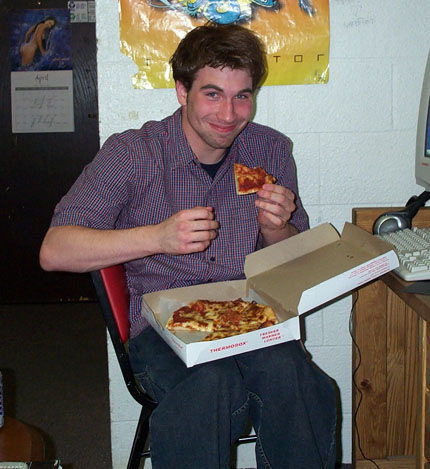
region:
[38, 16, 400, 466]
Man with an open pizza box in his hand.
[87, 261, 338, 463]
A red and black chair.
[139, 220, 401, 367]
Pizza box with an open lid.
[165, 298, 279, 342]
A slice taken out of the pizza.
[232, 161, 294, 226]
A slice of pizza in the hand.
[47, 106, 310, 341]
A red and blue thin striped shirt.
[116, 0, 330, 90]
A yellow poster behind the man's head.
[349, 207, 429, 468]
A brown wooden desk.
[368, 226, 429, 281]
A white computer keyboard on top of the desk.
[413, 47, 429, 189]
Edge of a computer monitor.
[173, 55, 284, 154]
the head of a man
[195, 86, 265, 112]
the eyes of a man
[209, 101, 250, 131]
the nose of a man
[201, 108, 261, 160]
the mouth of a man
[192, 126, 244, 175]
the chin of a man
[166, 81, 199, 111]
the ear of a man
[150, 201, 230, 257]
the hand of a man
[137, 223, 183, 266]
the wrist of a man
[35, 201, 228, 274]
the arm of a man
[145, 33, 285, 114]
the hair of a man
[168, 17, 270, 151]
this young man looks very pleased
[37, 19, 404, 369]
young man enjoying a pizza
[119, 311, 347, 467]
young man wearing baggy jeans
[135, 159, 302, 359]
young man is on his first slice of pizza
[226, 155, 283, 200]
pizza slice is half eaten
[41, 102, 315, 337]
young man wearing a checkered shirt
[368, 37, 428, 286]
young man has a desktop computer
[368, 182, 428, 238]
young man has a pair of over-ear headphones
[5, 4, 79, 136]
young man has a girlie calendar on the wall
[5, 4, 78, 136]
young man's girlie calendar is displaying April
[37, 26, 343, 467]
man eating slice of pizza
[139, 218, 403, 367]
box with pizza inside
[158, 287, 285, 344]
white paper liner underneath pizza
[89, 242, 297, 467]
red and black chair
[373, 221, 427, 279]
white keyboard for computer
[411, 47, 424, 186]
desktop computer on desk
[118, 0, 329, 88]
yellow and blue poster on wall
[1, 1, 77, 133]
calendar with woman posing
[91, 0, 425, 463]
white wall made of concrete blocks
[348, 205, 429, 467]
wood desk with computer on top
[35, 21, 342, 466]
Man eating a piece of pizza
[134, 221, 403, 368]
Box of pizza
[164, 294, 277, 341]
Pizza with one slice missing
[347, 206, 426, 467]
Part of a wooden computer stand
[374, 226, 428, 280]
White computer keyboard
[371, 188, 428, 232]
Half of a pair of computer earphones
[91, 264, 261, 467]
Red chair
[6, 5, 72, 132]
Calendar on the wall showing the month of April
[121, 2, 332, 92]
Yellow poster hanging on a wall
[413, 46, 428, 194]
The edge of a computer monitor